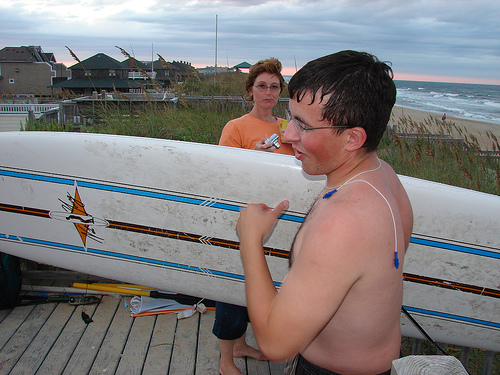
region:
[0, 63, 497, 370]
Man holding a surfboard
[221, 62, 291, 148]
Woman holding a camera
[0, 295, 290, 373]
Wooden boardwalk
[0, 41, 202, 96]
Beach houses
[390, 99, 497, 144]
Stretch of sand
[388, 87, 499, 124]
Waves crashing to shore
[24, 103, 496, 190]
Beach grass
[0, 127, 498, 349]
Dirty red, white and blue surfboard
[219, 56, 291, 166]
Woman wearing glasses and an orange shirt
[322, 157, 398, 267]
String around man's neck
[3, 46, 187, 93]
houses in the background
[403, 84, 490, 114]
waves in the water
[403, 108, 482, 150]
sand on the beach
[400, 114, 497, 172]
tall grass behind the people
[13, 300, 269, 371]
a wooden dock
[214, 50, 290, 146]
a lady in an orange shirt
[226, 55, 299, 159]
a lady holding a camera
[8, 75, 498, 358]
a man holding a white surfboard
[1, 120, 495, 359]
a white surfboard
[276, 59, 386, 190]
a man wearing glasses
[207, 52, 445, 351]
boy carrying his surfboard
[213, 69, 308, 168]
woman holding a camera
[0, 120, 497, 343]
surfboard being carried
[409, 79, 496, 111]
waves crashing on the shore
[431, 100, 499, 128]
water washing up on the beach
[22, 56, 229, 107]
houses along the shore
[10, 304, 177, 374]
wooden dock or walkway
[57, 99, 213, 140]
tall grasses between the beach and houses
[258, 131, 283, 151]
a small digital camera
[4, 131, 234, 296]
a surfboard with stripes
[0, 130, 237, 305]
a white surfboard with stripes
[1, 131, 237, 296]
a surfboard with blue stripes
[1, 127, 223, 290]
a surfboard with orange stripes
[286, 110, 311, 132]
a kid wearing glasses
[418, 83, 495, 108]
waves crashing in the distance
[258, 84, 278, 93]
woman wearing eye glasses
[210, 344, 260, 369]
a woman wearing no shoes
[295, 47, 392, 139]
a boy's wet hair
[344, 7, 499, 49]
blue cloudy sky in the distance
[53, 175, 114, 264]
design on white surfboard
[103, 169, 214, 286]
blue and orange stripes on surfboard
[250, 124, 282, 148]
small silver camera being held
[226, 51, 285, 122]
woman wearing eye glasses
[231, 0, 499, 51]
sky filled with white clouds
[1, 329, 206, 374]
brown wooden deck boarding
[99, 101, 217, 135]
bushes covered in green leaves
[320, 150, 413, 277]
pair of earplugs around neck of surfer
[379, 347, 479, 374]
top of wooden guardrail post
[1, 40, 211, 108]
row of houses in distance